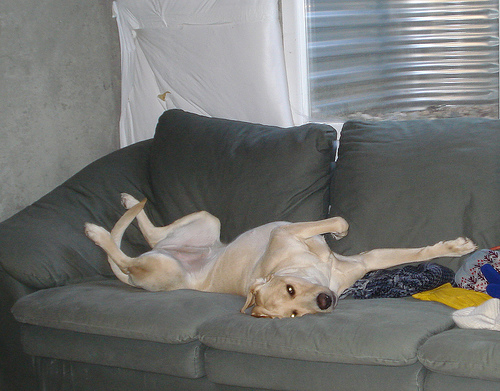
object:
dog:
[84, 191, 479, 322]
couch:
[0, 108, 496, 390]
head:
[241, 275, 336, 319]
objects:
[343, 260, 451, 298]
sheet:
[112, 4, 301, 149]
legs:
[119, 190, 205, 248]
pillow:
[322, 117, 498, 280]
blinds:
[300, 2, 499, 128]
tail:
[104, 196, 146, 285]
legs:
[82, 218, 176, 292]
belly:
[176, 224, 240, 279]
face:
[248, 273, 326, 319]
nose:
[312, 292, 333, 311]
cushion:
[12, 278, 246, 381]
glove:
[409, 283, 490, 311]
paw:
[328, 216, 350, 241]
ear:
[239, 280, 264, 310]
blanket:
[334, 261, 457, 299]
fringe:
[343, 275, 382, 304]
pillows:
[150, 108, 336, 255]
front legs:
[353, 235, 477, 272]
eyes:
[285, 284, 299, 298]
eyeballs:
[287, 308, 301, 317]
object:
[449, 298, 499, 332]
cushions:
[198, 279, 457, 390]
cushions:
[413, 318, 495, 390]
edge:
[11, 293, 494, 391]